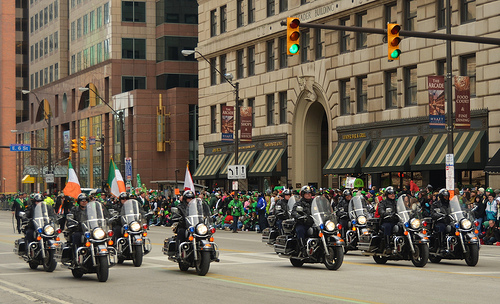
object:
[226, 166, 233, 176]
arrows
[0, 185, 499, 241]
crowd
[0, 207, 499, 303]
ground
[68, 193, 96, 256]
person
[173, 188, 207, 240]
person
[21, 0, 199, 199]
building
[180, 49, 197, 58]
street light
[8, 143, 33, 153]
sign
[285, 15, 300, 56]
traffic light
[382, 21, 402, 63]
traffic light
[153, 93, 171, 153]
plane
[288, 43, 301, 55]
light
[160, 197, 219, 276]
motorbikes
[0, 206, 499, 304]
road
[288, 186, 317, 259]
man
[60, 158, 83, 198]
flag